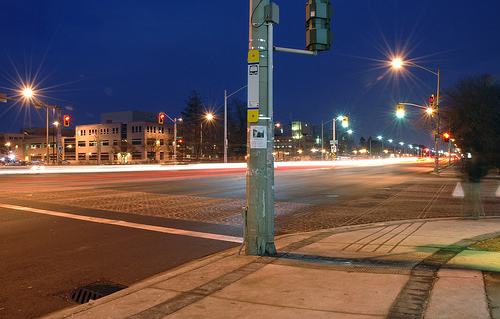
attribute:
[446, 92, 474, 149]
leaves — GREEN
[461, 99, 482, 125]
leaves — GREEN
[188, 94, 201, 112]
leaves — GREEN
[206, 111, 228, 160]
leaves — GREEN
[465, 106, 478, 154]
leaves — GREEN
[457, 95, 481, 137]
leaves — GREEN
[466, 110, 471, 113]
leaf — GREEN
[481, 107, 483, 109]
leaf — GREEN